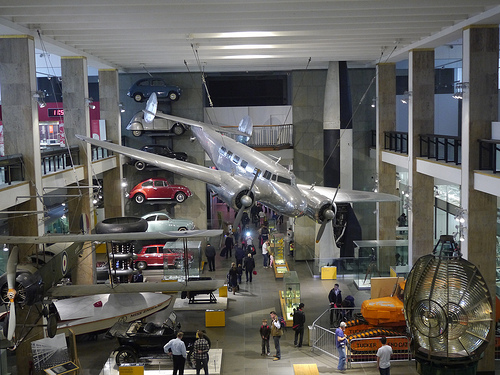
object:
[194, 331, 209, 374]
man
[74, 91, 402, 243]
airplane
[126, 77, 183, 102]
vw bug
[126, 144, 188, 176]
vw bug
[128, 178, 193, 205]
vw bug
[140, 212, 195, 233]
vw bug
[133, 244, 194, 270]
vw bug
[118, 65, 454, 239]
wall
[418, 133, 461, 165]
railing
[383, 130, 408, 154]
railing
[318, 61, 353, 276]
rocket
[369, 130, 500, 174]
platform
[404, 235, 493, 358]
fan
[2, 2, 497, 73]
ceiling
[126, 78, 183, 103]
car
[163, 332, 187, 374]
man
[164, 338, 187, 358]
shirt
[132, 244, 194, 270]
car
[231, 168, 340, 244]
propellers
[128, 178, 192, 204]
car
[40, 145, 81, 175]
bar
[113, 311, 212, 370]
car